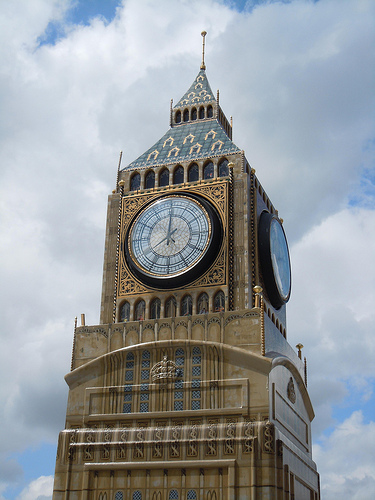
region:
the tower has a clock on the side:
[132, 195, 215, 285]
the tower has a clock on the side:
[261, 209, 293, 312]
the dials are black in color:
[155, 210, 179, 249]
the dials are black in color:
[276, 246, 289, 267]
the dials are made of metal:
[152, 211, 179, 249]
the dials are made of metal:
[276, 241, 288, 268]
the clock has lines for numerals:
[127, 199, 211, 275]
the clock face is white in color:
[130, 195, 209, 279]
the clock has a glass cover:
[130, 196, 209, 279]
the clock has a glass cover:
[268, 216, 295, 304]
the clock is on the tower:
[121, 191, 223, 285]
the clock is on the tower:
[259, 203, 291, 309]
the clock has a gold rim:
[127, 193, 209, 278]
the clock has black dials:
[148, 204, 180, 251]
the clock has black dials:
[275, 247, 287, 267]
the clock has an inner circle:
[150, 213, 191, 258]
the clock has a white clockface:
[133, 195, 216, 279]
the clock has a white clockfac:
[265, 213, 291, 307]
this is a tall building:
[35, 25, 323, 496]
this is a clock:
[124, 193, 214, 285]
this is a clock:
[263, 209, 302, 310]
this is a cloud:
[15, 254, 45, 302]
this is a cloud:
[286, 145, 332, 211]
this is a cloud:
[331, 427, 371, 485]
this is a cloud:
[20, 149, 74, 227]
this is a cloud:
[269, 125, 334, 208]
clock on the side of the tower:
[125, 193, 220, 287]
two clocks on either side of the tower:
[115, 182, 306, 315]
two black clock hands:
[142, 204, 186, 254]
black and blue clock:
[122, 187, 221, 291]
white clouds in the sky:
[0, 0, 372, 498]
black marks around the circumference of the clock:
[125, 198, 225, 279]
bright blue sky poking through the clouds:
[313, 382, 374, 439]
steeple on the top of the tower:
[194, 22, 211, 69]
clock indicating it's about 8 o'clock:
[124, 184, 223, 291]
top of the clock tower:
[196, 24, 213, 73]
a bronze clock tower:
[46, 115, 326, 495]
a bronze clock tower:
[61, 58, 312, 489]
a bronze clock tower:
[77, 86, 289, 495]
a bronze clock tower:
[51, 96, 319, 497]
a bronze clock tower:
[39, 84, 312, 491]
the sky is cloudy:
[22, 83, 135, 301]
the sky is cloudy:
[15, 120, 106, 336]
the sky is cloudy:
[2, 94, 133, 427]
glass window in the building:
[130, 172, 139, 189]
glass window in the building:
[142, 167, 154, 187]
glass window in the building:
[158, 168, 169, 185]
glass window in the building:
[171, 163, 185, 183]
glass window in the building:
[186, 160, 197, 181]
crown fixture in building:
[144, 343, 185, 386]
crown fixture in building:
[140, 346, 187, 383]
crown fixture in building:
[138, 342, 194, 385]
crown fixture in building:
[139, 341, 189, 382]